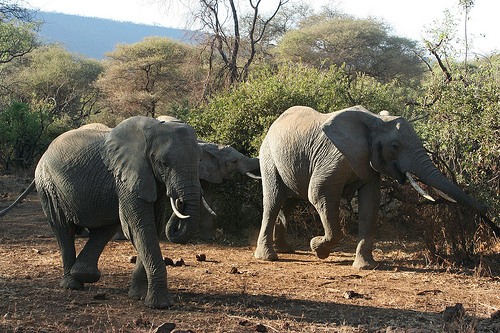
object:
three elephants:
[0, 104, 487, 310]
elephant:
[254, 105, 488, 270]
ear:
[319, 109, 384, 181]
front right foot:
[306, 156, 349, 258]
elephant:
[0, 115, 217, 309]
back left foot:
[70, 254, 102, 283]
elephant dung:
[194, 251, 206, 261]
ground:
[0, 191, 499, 333]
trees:
[89, 36, 211, 118]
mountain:
[0, 7, 233, 61]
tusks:
[169, 196, 191, 218]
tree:
[186, 0, 289, 91]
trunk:
[398, 142, 490, 217]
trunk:
[164, 165, 203, 243]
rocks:
[152, 321, 176, 332]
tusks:
[405, 171, 436, 201]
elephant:
[197, 139, 260, 240]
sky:
[0, 0, 499, 63]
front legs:
[350, 171, 380, 269]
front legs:
[116, 178, 176, 309]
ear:
[99, 115, 159, 202]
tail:
[0, 177, 36, 216]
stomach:
[267, 128, 309, 199]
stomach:
[43, 159, 118, 228]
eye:
[390, 140, 401, 151]